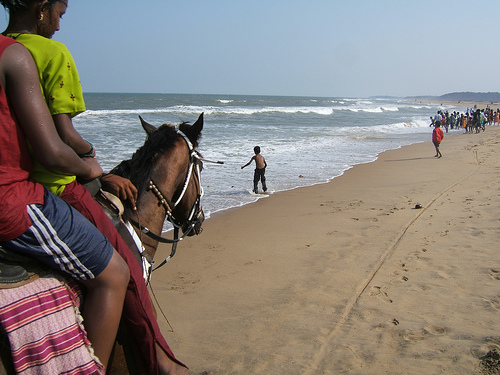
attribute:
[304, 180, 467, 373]
tracks — one-wheel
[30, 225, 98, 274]
shorts — blue, white, striped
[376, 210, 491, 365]
sand — tan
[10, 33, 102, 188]
shirt — green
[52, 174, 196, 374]
pants — red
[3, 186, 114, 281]
shorts — gray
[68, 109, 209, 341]
horse — brown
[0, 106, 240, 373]
horse — brown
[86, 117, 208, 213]
mane — dark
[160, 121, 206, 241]
harness — white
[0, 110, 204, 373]
horse — brown, black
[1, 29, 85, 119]
shirt — yellowish green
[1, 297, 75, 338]
blanket — colorful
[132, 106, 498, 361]
beach — sandy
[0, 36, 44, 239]
shirt — red, sleeveless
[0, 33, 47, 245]
tank top — red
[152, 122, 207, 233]
bridle — white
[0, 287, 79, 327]
stripe — purple, pink, orange, green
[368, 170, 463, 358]
footprints — small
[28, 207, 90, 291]
stripe — white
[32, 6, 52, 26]
earring — golden